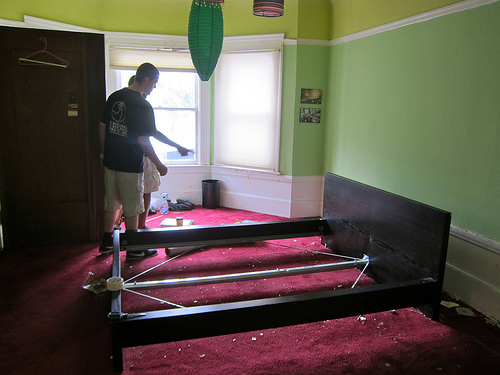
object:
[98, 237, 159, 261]
shoes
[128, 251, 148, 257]
logo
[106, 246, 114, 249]
logo 2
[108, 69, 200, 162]
window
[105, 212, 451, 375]
frame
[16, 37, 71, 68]
clothes hanger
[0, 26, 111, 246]
door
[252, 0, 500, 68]
molding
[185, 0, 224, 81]
light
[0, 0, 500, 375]
house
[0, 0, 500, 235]
wall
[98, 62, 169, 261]
man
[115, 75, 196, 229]
man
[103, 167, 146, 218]
shorts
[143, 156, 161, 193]
shorts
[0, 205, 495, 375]
carpet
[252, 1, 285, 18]
light fixture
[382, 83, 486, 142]
flag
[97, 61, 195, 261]
athletic trainers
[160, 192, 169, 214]
spray cleaner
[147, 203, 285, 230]
floor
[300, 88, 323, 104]
picture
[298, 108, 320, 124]
picture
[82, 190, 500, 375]
cleaner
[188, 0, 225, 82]
green decoration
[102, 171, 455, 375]
bed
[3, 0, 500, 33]
ceiling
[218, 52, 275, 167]
blind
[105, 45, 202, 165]
bay window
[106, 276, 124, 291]
tape